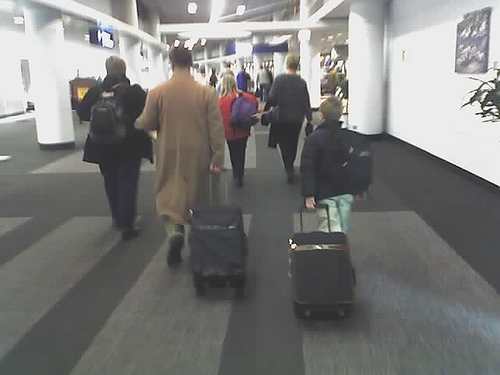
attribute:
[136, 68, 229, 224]
coat — long, light brown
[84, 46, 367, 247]
people — walking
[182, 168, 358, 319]
suitcases — rolling, black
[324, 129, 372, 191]
backpack — black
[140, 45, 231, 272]
man — dragging, walking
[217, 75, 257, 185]
woman — blonde, carrying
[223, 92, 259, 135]
backpack — purple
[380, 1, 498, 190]
wall — white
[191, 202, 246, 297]
suitcase — black, gray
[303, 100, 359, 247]
boy — dragging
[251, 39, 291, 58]
banner — purple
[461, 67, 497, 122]
plant — present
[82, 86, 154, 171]
coat — black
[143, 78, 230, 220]
coat — brown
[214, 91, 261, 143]
coat — red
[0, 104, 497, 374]
floor — gray